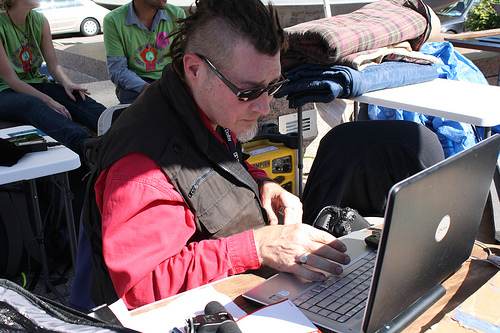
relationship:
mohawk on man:
[162, 0, 284, 79] [69, 0, 352, 318]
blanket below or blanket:
[274, 61, 440, 110] [278, 0, 442, 71]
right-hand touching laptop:
[253, 222, 351, 282] [241, 133, 498, 332]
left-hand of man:
[258, 179, 304, 223] [69, 0, 352, 318]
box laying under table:
[242, 133, 295, 195] [358, 78, 499, 126]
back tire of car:
[79, 18, 100, 36] [34, 0, 111, 36]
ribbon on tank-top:
[18, 47, 33, 73] [0, 8, 54, 92]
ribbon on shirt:
[140, 45, 160, 72] [105, 2, 186, 80]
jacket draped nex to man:
[301, 119, 445, 221] [69, 0, 352, 318]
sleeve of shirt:
[95, 153, 264, 311] [93, 154, 261, 309]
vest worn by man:
[71, 62, 271, 317] [69, 0, 352, 318]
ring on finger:
[300, 254, 308, 268] [297, 249, 344, 276]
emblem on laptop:
[431, 213, 450, 243] [241, 133, 498, 332]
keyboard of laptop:
[293, 248, 381, 323] [241, 133, 498, 332]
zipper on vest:
[189, 165, 216, 195] [71, 62, 271, 317]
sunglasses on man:
[237, 78, 290, 101] [69, 0, 352, 318]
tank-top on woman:
[0, 8, 54, 92] [1, 1, 107, 159]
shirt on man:
[105, 2, 186, 80] [104, 0, 188, 104]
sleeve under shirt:
[107, 55, 147, 93] [105, 2, 186, 80]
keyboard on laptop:
[293, 248, 381, 323] [241, 133, 498, 332]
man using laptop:
[69, 0, 352, 318] [241, 133, 498, 332]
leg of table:
[293, 105, 304, 199] [358, 78, 499, 126]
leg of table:
[354, 99, 359, 121] [358, 78, 499, 126]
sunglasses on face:
[237, 78, 290, 101] [234, 41, 281, 141]